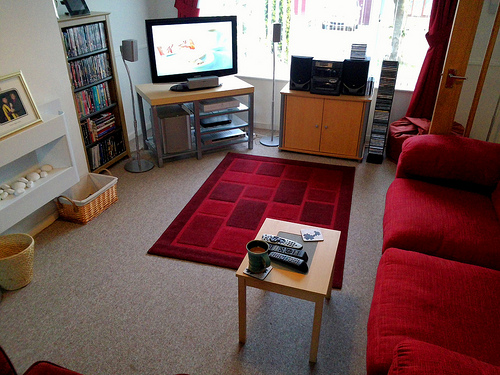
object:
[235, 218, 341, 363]
table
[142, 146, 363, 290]
rug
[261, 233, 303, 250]
remote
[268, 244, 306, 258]
remote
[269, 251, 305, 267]
remote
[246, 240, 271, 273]
coffee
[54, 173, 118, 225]
basket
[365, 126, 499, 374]
couch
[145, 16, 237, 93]
television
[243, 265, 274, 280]
coaster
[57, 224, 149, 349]
floor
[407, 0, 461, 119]
curtain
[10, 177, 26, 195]
rocks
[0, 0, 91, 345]
shelf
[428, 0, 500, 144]
door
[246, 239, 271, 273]
mug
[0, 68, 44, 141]
frame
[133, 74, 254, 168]
stand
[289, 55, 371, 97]
stereo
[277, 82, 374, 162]
cabinet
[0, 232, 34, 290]
basket